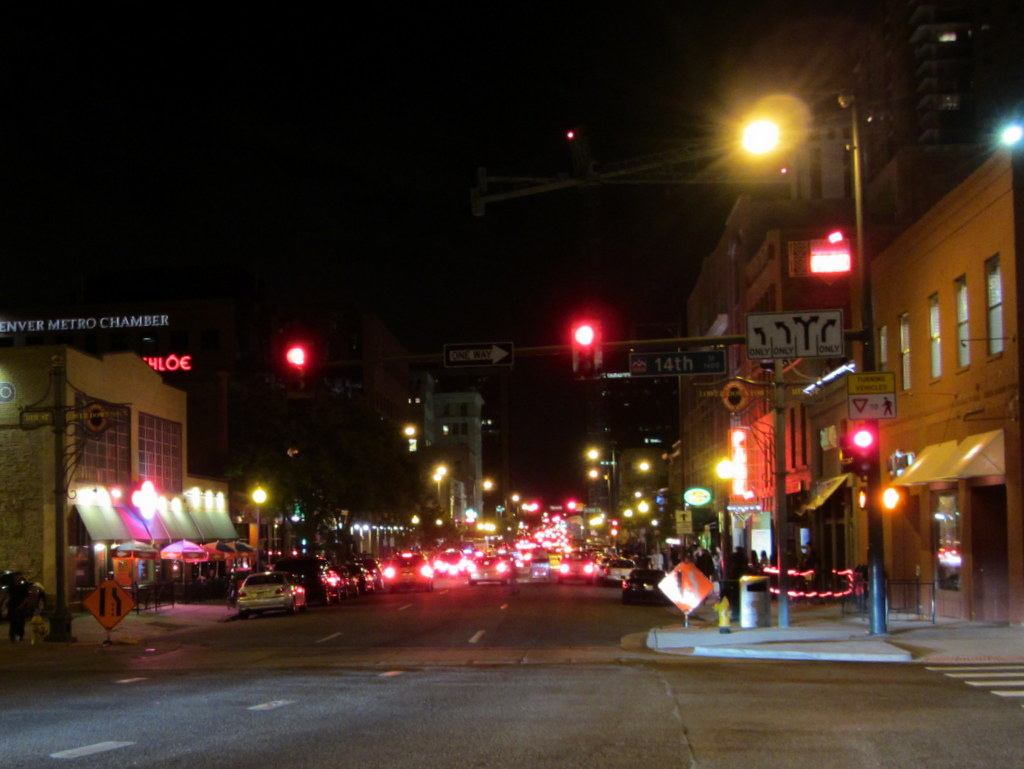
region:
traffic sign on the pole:
[599, 342, 733, 378]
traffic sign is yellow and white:
[849, 366, 901, 427]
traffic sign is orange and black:
[648, 556, 722, 624]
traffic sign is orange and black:
[68, 568, 135, 632]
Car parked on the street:
[226, 563, 293, 611]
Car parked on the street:
[281, 546, 342, 600]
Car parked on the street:
[618, 565, 657, 598]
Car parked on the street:
[334, 546, 364, 585]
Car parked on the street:
[549, 544, 600, 589]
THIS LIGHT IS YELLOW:
[709, 92, 804, 195]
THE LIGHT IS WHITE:
[984, 108, 1019, 160]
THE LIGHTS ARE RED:
[258, 298, 658, 404]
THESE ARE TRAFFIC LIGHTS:
[256, 288, 627, 413]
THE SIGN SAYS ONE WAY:
[421, 326, 523, 381]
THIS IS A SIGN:
[424, 324, 522, 381]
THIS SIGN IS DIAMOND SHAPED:
[621, 551, 720, 647]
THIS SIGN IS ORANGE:
[650, 543, 727, 629]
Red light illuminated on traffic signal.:
[272, 338, 330, 377]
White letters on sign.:
[2, 307, 186, 340]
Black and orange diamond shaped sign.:
[79, 574, 149, 631]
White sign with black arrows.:
[749, 309, 849, 354]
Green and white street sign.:
[626, 341, 740, 373]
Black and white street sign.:
[438, 332, 524, 375]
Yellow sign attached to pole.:
[838, 363, 899, 396]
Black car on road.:
[618, 556, 676, 620]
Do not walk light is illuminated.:
[878, 474, 916, 516]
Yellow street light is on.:
[237, 478, 285, 510]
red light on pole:
[536, 271, 680, 385]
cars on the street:
[324, 481, 625, 638]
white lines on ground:
[252, 623, 455, 766]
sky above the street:
[274, 155, 506, 332]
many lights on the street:
[328, 456, 643, 628]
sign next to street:
[603, 497, 756, 650]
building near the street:
[18, 306, 233, 620]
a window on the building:
[983, 262, 1022, 329]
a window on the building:
[952, 274, 973, 342]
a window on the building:
[898, 278, 938, 390]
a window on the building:
[891, 311, 930, 406]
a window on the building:
[769, 394, 799, 459]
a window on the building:
[145, 425, 177, 471]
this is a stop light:
[247, 294, 895, 491]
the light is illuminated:
[246, 304, 342, 416]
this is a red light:
[553, 303, 610, 361]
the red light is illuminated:
[834, 413, 889, 456]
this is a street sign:
[618, 347, 742, 383]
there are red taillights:
[353, 506, 648, 636]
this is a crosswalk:
[916, 648, 1019, 718]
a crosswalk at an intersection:
[100, 609, 745, 720]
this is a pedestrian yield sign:
[843, 370, 910, 431]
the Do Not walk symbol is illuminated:
[872, 473, 927, 524]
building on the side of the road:
[836, 162, 1015, 646]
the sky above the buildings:
[26, 13, 663, 304]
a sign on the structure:
[737, 298, 859, 366]